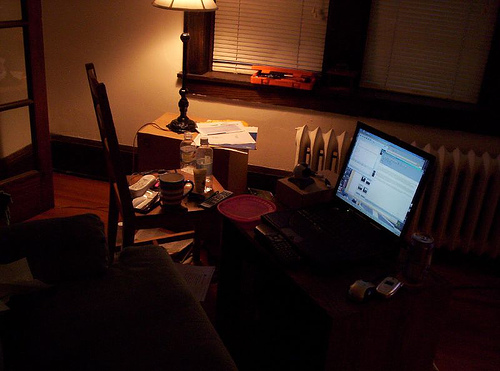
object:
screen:
[332, 127, 428, 236]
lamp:
[149, 0, 218, 134]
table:
[135, 109, 249, 196]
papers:
[195, 122, 245, 135]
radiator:
[292, 123, 499, 262]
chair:
[83, 60, 234, 279]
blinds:
[359, 0, 499, 104]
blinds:
[211, 1, 328, 81]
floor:
[8, 165, 498, 370]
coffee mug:
[157, 172, 196, 210]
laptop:
[260, 119, 436, 264]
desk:
[214, 188, 449, 371]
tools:
[250, 63, 316, 92]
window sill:
[177, 68, 499, 138]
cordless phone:
[129, 171, 169, 197]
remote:
[200, 189, 233, 210]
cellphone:
[375, 274, 405, 298]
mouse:
[344, 277, 376, 304]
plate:
[217, 194, 277, 224]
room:
[1, 1, 497, 370]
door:
[1, 0, 58, 230]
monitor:
[331, 120, 436, 239]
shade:
[152, 0, 219, 13]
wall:
[39, 1, 499, 196]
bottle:
[192, 144, 213, 192]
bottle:
[178, 131, 197, 187]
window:
[202, 1, 334, 90]